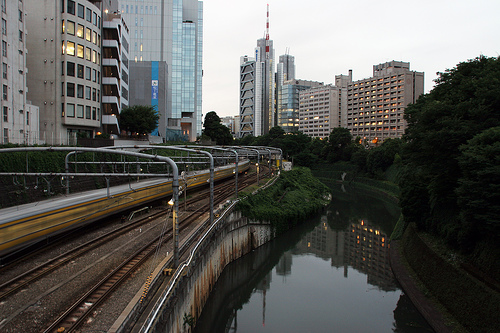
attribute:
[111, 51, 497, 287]
trees — green